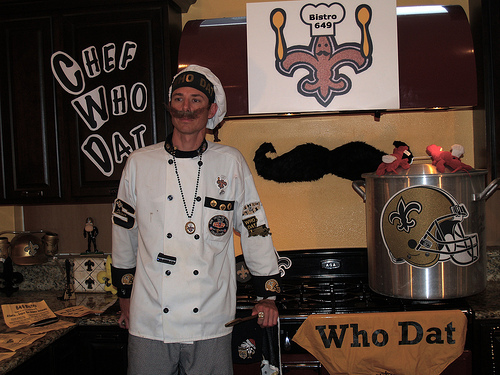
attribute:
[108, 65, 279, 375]
man — chef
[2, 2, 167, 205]
cupboard — black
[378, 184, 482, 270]
logo — football team, new orleans saints, football helmet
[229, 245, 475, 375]
stove — black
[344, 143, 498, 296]
pot — huge, large, metal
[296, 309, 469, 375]
towel — black, orange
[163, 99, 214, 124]
fake mustache — black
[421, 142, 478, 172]
crawdad — plush, red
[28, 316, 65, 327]
handle — black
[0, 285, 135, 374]
counter — marble, brown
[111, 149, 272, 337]
chef's jacket — emblazoned, decorated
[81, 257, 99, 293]
spades — black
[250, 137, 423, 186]
mustache — black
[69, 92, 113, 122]
w — black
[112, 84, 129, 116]
h — black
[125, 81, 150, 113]
o — black, lowercase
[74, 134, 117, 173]
d — black, capitalized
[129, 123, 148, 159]
t — black